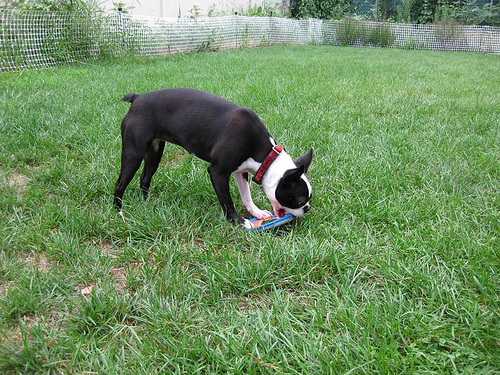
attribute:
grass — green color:
[337, 74, 484, 174]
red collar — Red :
[248, 137, 279, 183]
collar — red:
[246, 132, 292, 184]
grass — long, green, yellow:
[0, 38, 494, 371]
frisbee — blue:
[242, 212, 295, 233]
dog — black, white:
[110, 87, 317, 230]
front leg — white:
[232, 169, 272, 220]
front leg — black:
[206, 162, 254, 229]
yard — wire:
[1, 43, 484, 373]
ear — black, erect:
[282, 161, 307, 190]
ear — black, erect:
[292, 144, 314, 173]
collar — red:
[251, 142, 284, 185]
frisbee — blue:
[232, 210, 294, 236]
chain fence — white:
[1, 8, 484, 72]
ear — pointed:
[276, 162, 306, 191]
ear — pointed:
[292, 146, 315, 174]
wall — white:
[1, 1, 292, 41]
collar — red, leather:
[249, 144, 287, 180]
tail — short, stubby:
[115, 89, 135, 103]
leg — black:
[108, 121, 135, 209]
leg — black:
[140, 138, 165, 191]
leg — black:
[209, 156, 236, 224]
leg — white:
[233, 174, 264, 221]